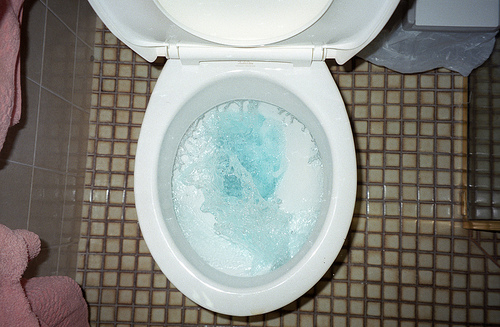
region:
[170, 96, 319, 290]
Blue cleaning product and water being flushed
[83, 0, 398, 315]
A clean, white toilet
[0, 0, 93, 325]
A pink towel hanging beside the toilet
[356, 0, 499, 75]
A garbage bin beside the toilet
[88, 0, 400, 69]
The toilet seat, lifted up.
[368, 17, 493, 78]
The bag in the trash bin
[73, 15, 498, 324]
A dirty, beige, tiled floor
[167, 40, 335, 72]
The white hinge of the toilet lid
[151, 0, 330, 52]
The toilet lid visible through the seat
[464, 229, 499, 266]
A spot in the floor where the tiles don't match up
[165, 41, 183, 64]
the hinge of a toilet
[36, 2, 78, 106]
a brown tile on the wall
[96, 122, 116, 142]
a small white floor tile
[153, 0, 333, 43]
the lid of a toilet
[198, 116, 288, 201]
blue water in the toilet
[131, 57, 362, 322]
a white toilet bowl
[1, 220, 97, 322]
a pink towel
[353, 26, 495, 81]
a white plastic bag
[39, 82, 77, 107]
white caulking on the wall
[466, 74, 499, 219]
a reflection on the wall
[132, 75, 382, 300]
blue foam in toilet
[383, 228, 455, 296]
this tile is gross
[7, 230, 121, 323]
there is a pink towel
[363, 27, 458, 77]
the trash bag is white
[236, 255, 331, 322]
the toilet is white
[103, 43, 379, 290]
the toilet is flushing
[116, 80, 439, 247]
the seat is up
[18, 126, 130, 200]
the wall tile is brown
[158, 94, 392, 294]
the water is moving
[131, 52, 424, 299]
the activity is cleaning the toilet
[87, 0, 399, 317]
a white toilet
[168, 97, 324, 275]
water being flushed in the toilet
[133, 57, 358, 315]
the bowl of the toilet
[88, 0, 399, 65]
the lid of the toilet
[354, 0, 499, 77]
a white trash can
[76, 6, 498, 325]
small tiles on the floor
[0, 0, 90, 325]
pink towels hanging on the wall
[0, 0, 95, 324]
larger tiles on the wall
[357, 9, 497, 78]
a white trash bag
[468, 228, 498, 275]
a diagonal line on the tiles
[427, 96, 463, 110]
part of a floor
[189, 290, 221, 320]
edge of a toilet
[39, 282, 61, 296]
part of a towel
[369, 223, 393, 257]
part of a square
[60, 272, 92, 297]
edge of a towel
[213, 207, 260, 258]
part of some foam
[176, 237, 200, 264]
edge of a toilet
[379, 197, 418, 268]
part of a floor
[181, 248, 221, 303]
part of a toilet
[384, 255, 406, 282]
part of a square